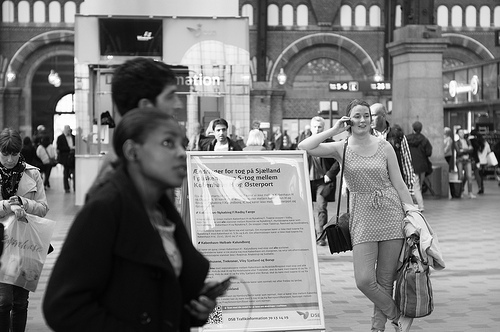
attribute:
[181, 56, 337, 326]
booth — information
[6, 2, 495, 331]
station — train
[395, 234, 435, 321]
purse — striped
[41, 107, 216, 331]
woman — looking at something, looking up, listening to music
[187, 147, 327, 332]
sign — white, large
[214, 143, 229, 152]
shirt — white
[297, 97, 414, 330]
woman — leaning, standing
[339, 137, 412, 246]
shirt — tied, polka dot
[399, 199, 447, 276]
coat — light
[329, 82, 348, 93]
numbers — white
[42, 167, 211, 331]
jacket — dark, black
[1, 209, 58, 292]
sack — plastic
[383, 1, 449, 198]
pillar — big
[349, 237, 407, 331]
woman's legs — crossed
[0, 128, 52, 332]
woman — looking down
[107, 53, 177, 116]
hair — black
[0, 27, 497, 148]
arches — made of stone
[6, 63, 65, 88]
three ceiling lights — lit, hanging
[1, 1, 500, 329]
picture — black